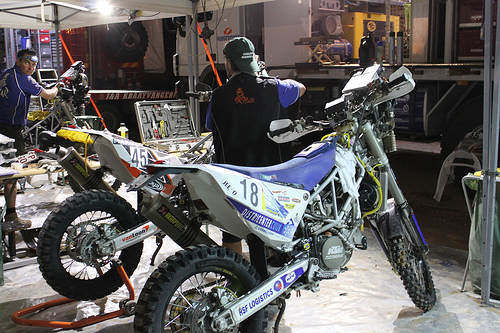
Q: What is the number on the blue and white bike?
A: 18.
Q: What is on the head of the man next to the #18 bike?
A: Baseball cap.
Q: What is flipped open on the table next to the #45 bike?
A: Tool box.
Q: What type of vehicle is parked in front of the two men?
A: Truck.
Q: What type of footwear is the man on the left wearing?
A: Work boots.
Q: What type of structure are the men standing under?
A: Canopy tent.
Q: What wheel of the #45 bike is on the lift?
A: Rear wheel.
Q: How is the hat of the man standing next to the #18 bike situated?
A: Backwards.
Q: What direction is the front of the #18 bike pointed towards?
A: Left.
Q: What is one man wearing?
A: Black cap.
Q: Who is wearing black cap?
A: The person.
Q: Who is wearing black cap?
A: The man.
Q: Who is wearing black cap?
A: The man.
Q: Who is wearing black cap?
A: The man.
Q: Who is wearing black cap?
A: The man.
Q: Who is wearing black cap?
A: The man.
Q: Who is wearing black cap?
A: The man.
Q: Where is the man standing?
A: Motorcycle.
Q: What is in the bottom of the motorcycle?
A: Wheel.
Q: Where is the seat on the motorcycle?
A: In the back.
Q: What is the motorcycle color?
A: Blue.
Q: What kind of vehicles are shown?
A: Motorcycles.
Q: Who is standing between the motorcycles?
A: A guy with a backwards hat.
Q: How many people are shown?
A: Two.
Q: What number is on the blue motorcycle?
A: 18.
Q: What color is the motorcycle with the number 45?
A: Red.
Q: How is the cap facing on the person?
A: Backwards.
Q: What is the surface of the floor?
A: Cement.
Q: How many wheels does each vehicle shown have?
A: Two.